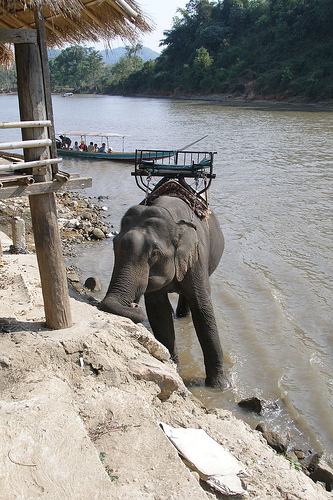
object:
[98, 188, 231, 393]
elephant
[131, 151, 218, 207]
basket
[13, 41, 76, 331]
pole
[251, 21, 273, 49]
tree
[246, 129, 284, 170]
river